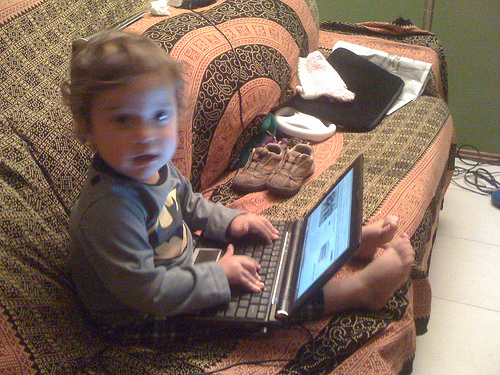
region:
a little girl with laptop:
[47, 43, 324, 334]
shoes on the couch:
[221, 116, 341, 228]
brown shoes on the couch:
[229, 138, 318, 195]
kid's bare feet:
[353, 213, 418, 315]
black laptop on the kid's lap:
[164, 148, 366, 325]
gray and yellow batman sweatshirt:
[66, 154, 246, 323]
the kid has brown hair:
[59, 27, 187, 143]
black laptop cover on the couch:
[288, 48, 405, 130]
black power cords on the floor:
[449, 141, 499, 201]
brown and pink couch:
[1, 0, 459, 372]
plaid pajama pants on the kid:
[92, 284, 327, 347]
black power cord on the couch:
[191, 8, 250, 165]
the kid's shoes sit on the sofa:
[226, 131, 318, 199]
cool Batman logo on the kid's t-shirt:
[142, 181, 193, 266]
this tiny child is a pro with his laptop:
[168, 149, 368, 334]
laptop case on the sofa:
[276, 41, 409, 139]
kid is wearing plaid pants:
[87, 281, 323, 350]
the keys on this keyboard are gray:
[176, 208, 298, 328]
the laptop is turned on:
[292, 152, 366, 319]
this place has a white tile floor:
[411, 148, 498, 374]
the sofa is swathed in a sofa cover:
[4, 2, 450, 374]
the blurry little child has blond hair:
[61, 25, 193, 142]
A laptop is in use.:
[182, 155, 362, 326]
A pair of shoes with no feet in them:
[232, 135, 312, 190]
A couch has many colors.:
[0, 0, 456, 370]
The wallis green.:
[310, 0, 495, 157]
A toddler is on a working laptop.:
[60, 35, 361, 345]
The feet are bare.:
[327, 213, 412, 316]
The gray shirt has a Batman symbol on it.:
[62, 162, 242, 316]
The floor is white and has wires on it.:
[407, 160, 497, 374]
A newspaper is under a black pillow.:
[332, 45, 441, 120]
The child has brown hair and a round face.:
[56, 30, 184, 180]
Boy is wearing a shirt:
[55, 158, 245, 310]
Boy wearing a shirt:
[67, 154, 237, 317]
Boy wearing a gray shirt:
[61, 152, 246, 321]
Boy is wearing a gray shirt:
[57, 157, 244, 323]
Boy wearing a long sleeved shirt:
[63, 152, 245, 334]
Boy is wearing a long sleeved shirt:
[68, 145, 235, 320]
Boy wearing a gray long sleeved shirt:
[61, 147, 242, 322]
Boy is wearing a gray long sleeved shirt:
[67, 152, 242, 323]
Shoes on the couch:
[229, 140, 321, 192]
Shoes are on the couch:
[222, 139, 322, 196]